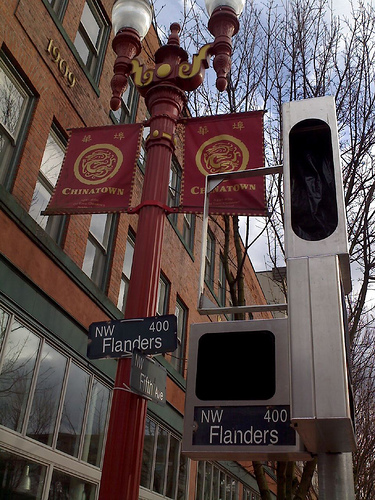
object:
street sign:
[87, 314, 178, 361]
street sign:
[128, 348, 166, 405]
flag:
[178, 110, 271, 218]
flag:
[40, 122, 143, 216]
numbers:
[45, 36, 76, 88]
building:
[1, 1, 318, 500]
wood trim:
[43, 0, 317, 499]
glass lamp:
[109, 1, 155, 42]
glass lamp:
[204, 0, 247, 17]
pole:
[99, 0, 240, 498]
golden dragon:
[74, 143, 123, 185]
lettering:
[95, 320, 170, 353]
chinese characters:
[82, 130, 126, 144]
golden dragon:
[194, 135, 249, 173]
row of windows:
[0, 301, 261, 499]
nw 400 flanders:
[95, 319, 169, 352]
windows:
[0, 42, 42, 192]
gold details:
[128, 43, 212, 140]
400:
[149, 320, 170, 333]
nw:
[94, 325, 115, 337]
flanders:
[102, 337, 162, 353]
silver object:
[281, 93, 348, 259]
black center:
[289, 117, 338, 243]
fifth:
[140, 371, 155, 395]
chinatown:
[190, 183, 256, 195]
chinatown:
[62, 187, 125, 195]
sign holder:
[196, 164, 288, 316]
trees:
[142, 1, 375, 500]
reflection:
[1, 60, 262, 500]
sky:
[150, 0, 374, 499]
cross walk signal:
[195, 331, 277, 402]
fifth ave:
[139, 372, 164, 400]